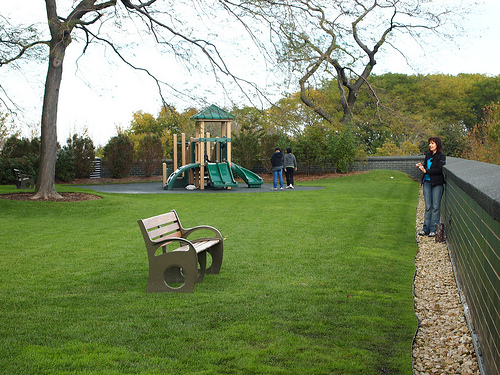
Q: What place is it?
A: It is a park.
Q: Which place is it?
A: It is a park.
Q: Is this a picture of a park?
A: Yes, it is showing a park.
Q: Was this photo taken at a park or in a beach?
A: It was taken at a park.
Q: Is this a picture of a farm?
A: No, the picture is showing a park.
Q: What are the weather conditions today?
A: It is cloudy.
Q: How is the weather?
A: It is cloudy.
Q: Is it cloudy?
A: Yes, it is cloudy.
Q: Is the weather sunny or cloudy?
A: It is cloudy.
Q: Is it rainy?
A: No, it is cloudy.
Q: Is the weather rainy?
A: No, it is cloudy.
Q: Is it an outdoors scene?
A: Yes, it is outdoors.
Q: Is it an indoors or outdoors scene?
A: It is outdoors.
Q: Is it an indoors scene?
A: No, it is outdoors.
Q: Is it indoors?
A: No, it is outdoors.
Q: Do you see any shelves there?
A: No, there are no shelves.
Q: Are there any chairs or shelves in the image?
A: No, there are no shelves or chairs.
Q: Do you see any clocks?
A: No, there are no clocks.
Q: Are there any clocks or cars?
A: No, there are no clocks or cars.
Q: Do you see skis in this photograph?
A: No, there are no skis.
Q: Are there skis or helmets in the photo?
A: No, there are no skis or helmets.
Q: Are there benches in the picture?
A: Yes, there is a bench.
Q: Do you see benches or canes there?
A: Yes, there is a bench.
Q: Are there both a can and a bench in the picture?
A: No, there is a bench but no cans.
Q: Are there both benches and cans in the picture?
A: No, there is a bench but no cans.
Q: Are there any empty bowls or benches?
A: Yes, there is an empty bench.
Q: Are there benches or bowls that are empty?
A: Yes, the bench is empty.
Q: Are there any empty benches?
A: Yes, there is an empty bench.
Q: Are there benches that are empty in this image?
A: Yes, there is an empty bench.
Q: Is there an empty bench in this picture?
A: Yes, there is an empty bench.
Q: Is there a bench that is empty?
A: Yes, there is a bench that is empty.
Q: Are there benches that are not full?
A: Yes, there is a empty bench.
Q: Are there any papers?
A: No, there are no papers.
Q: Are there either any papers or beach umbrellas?
A: No, there are no papers or beach umbrellas.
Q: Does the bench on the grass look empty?
A: Yes, the bench is empty.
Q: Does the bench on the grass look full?
A: No, the bench is empty.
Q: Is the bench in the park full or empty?
A: The bench is empty.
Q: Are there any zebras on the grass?
A: No, there is a bench on the grass.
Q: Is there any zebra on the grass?
A: No, there is a bench on the grass.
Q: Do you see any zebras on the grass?
A: No, there is a bench on the grass.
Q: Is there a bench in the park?
A: Yes, there is a bench in the park.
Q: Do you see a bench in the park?
A: Yes, there is a bench in the park.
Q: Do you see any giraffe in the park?
A: No, there is a bench in the park.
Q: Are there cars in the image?
A: No, there are no cars.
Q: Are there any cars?
A: No, there are no cars.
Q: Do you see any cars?
A: No, there are no cars.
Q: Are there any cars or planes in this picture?
A: No, there are no cars or planes.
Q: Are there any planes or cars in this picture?
A: No, there are no cars or planes.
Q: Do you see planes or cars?
A: No, there are no cars or planes.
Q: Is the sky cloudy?
A: Yes, the sky is cloudy.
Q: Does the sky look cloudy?
A: Yes, the sky is cloudy.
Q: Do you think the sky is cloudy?
A: Yes, the sky is cloudy.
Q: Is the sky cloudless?
A: No, the sky is cloudy.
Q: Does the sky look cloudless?
A: No, the sky is cloudy.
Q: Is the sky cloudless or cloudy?
A: The sky is cloudy.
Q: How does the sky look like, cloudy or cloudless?
A: The sky is cloudy.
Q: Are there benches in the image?
A: Yes, there is a bench.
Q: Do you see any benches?
A: Yes, there is a bench.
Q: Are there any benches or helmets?
A: Yes, there is a bench.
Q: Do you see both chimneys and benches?
A: No, there is a bench but no chimneys.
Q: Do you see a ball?
A: No, there are no balls.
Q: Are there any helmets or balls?
A: No, there are no balls or helmets.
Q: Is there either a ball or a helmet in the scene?
A: No, there are no balls or helmets.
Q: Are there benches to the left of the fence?
A: Yes, there is a bench to the left of the fence.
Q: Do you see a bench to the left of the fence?
A: Yes, there is a bench to the left of the fence.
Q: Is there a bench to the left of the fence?
A: Yes, there is a bench to the left of the fence.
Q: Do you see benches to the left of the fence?
A: Yes, there is a bench to the left of the fence.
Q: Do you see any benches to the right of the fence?
A: No, the bench is to the left of the fence.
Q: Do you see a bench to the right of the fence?
A: No, the bench is to the left of the fence.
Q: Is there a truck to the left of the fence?
A: No, there is a bench to the left of the fence.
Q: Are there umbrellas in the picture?
A: No, there are no umbrellas.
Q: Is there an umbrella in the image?
A: No, there are no umbrellas.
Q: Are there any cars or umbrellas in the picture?
A: No, there are no umbrellas or cars.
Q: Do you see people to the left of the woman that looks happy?
A: Yes, there are people to the left of the woman.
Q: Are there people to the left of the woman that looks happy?
A: Yes, there are people to the left of the woman.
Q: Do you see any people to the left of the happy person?
A: Yes, there are people to the left of the woman.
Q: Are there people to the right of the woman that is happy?
A: No, the people are to the left of the woman.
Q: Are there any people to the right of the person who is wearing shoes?
A: No, the people are to the left of the woman.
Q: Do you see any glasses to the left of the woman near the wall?
A: No, there are people to the left of the woman.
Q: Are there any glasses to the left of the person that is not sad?
A: No, there are people to the left of the woman.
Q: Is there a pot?
A: No, there are no pots.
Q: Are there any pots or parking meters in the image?
A: No, there are no pots or parking meters.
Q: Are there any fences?
A: Yes, there is a fence.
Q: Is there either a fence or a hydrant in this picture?
A: Yes, there is a fence.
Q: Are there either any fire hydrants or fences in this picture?
A: Yes, there is a fence.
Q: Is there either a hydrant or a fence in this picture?
A: Yes, there is a fence.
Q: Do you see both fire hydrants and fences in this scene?
A: No, there is a fence but no fire hydrants.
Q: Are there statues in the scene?
A: No, there are no statues.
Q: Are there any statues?
A: No, there are no statues.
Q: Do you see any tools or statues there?
A: No, there are no statues or tools.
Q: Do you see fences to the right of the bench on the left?
A: Yes, there is a fence to the right of the bench.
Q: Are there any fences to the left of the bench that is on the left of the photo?
A: No, the fence is to the right of the bench.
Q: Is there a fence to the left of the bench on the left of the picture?
A: No, the fence is to the right of the bench.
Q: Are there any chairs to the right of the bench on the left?
A: No, there is a fence to the right of the bench.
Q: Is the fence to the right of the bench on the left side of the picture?
A: Yes, the fence is to the right of the bench.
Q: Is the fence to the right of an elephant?
A: No, the fence is to the right of the bench.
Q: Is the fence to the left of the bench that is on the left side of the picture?
A: No, the fence is to the right of the bench.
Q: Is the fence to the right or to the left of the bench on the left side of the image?
A: The fence is to the right of the bench.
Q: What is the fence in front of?
A: The fence is in front of the trees.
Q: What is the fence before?
A: The fence is in front of the trees.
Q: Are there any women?
A: Yes, there is a woman.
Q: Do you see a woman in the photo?
A: Yes, there is a woman.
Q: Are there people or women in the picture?
A: Yes, there is a woman.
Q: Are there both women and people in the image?
A: Yes, there are both a woman and people.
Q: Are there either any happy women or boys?
A: Yes, there is a happy woman.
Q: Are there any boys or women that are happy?
A: Yes, the woman is happy.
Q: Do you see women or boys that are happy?
A: Yes, the woman is happy.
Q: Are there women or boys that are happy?
A: Yes, the woman is happy.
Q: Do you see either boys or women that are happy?
A: Yes, the woman is happy.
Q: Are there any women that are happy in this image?
A: Yes, there is a happy woman.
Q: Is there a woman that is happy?
A: Yes, there is a woman that is happy.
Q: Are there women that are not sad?
A: Yes, there is a happy woman.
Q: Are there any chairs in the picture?
A: No, there are no chairs.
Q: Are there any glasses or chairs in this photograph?
A: No, there are no chairs or glasses.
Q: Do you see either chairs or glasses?
A: No, there are no chairs or glasses.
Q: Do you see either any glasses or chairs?
A: No, there are no chairs or glasses.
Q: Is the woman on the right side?
A: Yes, the woman is on the right of the image.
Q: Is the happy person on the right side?
A: Yes, the woman is on the right of the image.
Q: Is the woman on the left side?
A: No, the woman is on the right of the image.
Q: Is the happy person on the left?
A: No, the woman is on the right of the image.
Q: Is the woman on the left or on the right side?
A: The woman is on the right of the image.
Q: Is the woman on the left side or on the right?
A: The woman is on the right of the image.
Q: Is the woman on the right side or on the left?
A: The woman is on the right of the image.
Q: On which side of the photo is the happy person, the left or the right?
A: The woman is on the right of the image.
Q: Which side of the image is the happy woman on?
A: The woman is on the right of the image.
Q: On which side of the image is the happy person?
A: The woman is on the right of the image.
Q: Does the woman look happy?
A: Yes, the woman is happy.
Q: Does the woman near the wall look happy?
A: Yes, the woman is happy.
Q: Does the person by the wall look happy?
A: Yes, the woman is happy.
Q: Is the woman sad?
A: No, the woman is happy.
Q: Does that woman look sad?
A: No, the woman is happy.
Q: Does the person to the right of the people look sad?
A: No, the woman is happy.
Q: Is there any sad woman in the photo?
A: No, there is a woman but she is happy.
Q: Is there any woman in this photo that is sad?
A: No, there is a woman but she is happy.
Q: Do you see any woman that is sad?
A: No, there is a woman but she is happy.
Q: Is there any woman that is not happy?
A: No, there is a woman but she is happy.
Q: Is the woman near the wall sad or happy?
A: The woman is happy.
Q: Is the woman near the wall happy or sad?
A: The woman is happy.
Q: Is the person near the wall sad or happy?
A: The woman is happy.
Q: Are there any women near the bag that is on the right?
A: Yes, there is a woman near the bag.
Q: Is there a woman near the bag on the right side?
A: Yes, there is a woman near the bag.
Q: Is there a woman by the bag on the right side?
A: Yes, there is a woman by the bag.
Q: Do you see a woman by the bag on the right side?
A: Yes, there is a woman by the bag.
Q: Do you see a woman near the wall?
A: Yes, there is a woman near the wall.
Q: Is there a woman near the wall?
A: Yes, there is a woman near the wall.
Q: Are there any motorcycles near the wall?
A: No, there is a woman near the wall.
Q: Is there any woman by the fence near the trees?
A: Yes, there is a woman by the fence.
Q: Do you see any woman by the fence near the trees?
A: Yes, there is a woman by the fence.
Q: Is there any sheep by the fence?
A: No, there is a woman by the fence.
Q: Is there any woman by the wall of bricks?
A: Yes, there is a woman by the wall.